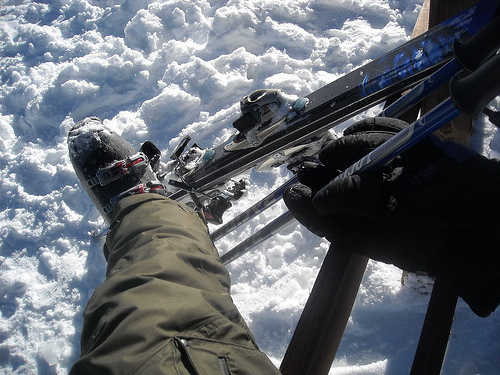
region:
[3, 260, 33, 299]
clump of white snow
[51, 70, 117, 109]
clump of white snow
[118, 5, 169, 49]
clump of white snow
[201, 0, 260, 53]
clump of white snow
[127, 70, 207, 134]
clump of white snow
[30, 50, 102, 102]
clump of white snow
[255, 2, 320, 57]
clump of white snow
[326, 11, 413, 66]
clump of white snow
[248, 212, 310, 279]
clump of white snow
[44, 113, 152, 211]
boot with snow on it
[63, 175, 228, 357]
puffy olive colored pants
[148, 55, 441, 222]
skis with snow on them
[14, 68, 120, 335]
broken up snow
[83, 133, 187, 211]
boot has red latches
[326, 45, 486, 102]
ski has blue design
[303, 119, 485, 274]
2 large black gloves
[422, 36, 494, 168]
skiing pole with black handle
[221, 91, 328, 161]
locking mechanism on ski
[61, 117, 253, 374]
Skier's leg standing in the snow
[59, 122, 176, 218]
Ski boot caked in snow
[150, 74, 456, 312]
Ski poles and skis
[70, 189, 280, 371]
Insulated ski pant leg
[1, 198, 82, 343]
Powdered white snow reflecting the sun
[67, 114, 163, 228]
Ski boot with red straps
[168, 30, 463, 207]
The skis are black with blue accents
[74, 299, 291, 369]
Pocket on the pantleg of the snow pants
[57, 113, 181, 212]
Foot with black shoe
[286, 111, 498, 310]
Hand with black glove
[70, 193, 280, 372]
Man's leg wearing a brown snow suit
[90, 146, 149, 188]
Velcro on a shoe with red stripe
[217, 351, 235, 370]
Small zipper on pants leg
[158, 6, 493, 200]
Black ski with blue decoration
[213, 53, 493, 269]
Black ski pole with a handle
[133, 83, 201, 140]
Snowball on the ground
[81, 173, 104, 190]
Buckle on snow boot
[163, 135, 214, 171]
Mechanical device on ski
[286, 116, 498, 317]
Large black ski glove holding onto pole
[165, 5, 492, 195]
Black ski with blue design on top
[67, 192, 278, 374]
Men's olive ski pants with zippers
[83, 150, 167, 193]
Grey and red straps on ski boots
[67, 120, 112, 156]
Snow on tip of black boot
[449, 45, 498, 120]
Black handle on end of ski pole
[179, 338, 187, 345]
Rivot on man's ski pants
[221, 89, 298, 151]
Metal attachment on black ski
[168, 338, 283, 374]
Pocket on front of man's ski pants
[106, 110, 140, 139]
A clump of snow.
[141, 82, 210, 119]
A clump of snow.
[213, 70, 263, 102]
A clump of snow.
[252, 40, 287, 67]
A clump of snow.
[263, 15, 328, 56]
A clump of snow.